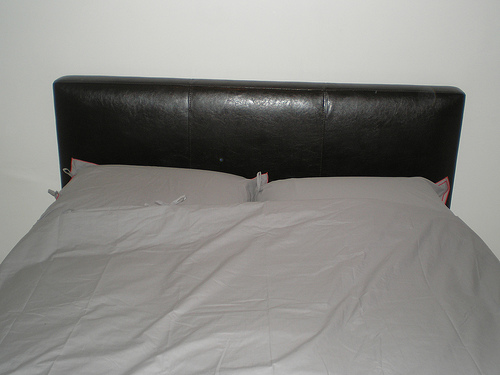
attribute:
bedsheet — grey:
[2, 201, 500, 374]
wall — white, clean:
[1, 0, 498, 267]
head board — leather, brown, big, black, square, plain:
[53, 75, 465, 217]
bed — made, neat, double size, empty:
[0, 76, 499, 374]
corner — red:
[71, 158, 89, 170]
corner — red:
[436, 176, 453, 194]